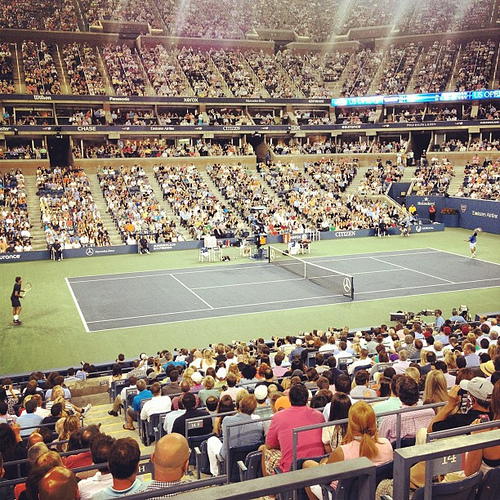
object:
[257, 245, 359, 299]
net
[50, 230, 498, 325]
court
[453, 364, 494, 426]
binoculars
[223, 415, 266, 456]
shirt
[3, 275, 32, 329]
tennis player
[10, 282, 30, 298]
shirt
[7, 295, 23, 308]
shorts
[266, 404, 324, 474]
pink shirt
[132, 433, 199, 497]
guy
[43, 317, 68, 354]
green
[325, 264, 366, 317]
symbol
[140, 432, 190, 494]
spectator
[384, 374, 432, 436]
spectator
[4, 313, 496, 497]
stand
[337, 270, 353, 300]
mercedes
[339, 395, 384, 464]
hair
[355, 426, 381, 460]
pony tail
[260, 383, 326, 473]
man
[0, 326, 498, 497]
spectators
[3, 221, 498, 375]
match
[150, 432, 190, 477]
head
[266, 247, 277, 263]
mercedes symbol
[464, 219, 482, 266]
tennis player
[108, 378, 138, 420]
man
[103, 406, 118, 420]
shoe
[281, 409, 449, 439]
railing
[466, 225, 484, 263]
player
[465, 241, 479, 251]
white shorts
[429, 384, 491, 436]
guy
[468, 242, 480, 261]
shorts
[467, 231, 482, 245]
shirt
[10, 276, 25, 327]
man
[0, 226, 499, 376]
court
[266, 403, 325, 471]
shirt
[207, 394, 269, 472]
man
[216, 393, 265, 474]
man